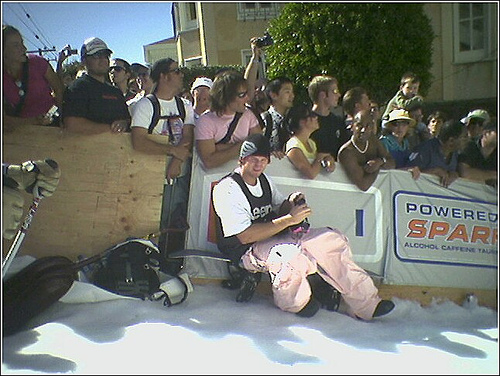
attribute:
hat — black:
[236, 132, 271, 162]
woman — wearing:
[280, 103, 337, 175]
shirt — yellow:
[279, 134, 324, 164]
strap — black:
[214, 108, 243, 145]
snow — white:
[2, 285, 497, 375]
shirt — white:
[210, 172, 296, 240]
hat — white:
[81, 37, 106, 53]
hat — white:
[197, 72, 212, 82]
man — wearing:
[209, 132, 396, 320]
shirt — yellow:
[284, 133, 318, 163]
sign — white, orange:
[390, 178, 495, 270]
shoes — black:
[312, 281, 412, 331]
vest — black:
[207, 172, 274, 255]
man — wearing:
[344, 114, 394, 198]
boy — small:
[392, 68, 444, 149]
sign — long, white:
[187, 148, 499, 300]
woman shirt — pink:
[1, 65, 60, 125]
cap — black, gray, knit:
[219, 130, 264, 162]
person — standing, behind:
[279, 100, 336, 179]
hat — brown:
[371, 103, 419, 130]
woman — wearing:
[270, 97, 339, 180]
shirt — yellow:
[279, 124, 327, 161]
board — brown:
[4, 122, 162, 269]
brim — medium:
[88, 51, 124, 53]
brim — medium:
[179, 79, 216, 95]